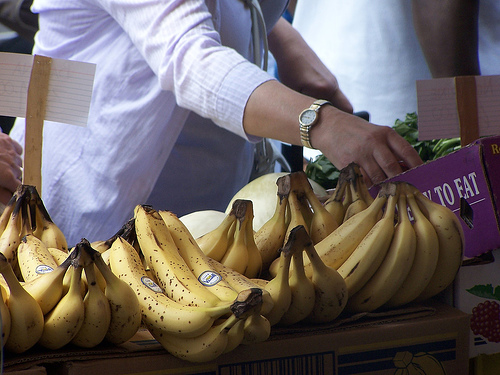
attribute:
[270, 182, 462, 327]
bananas — bunch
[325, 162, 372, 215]
bananas — bunch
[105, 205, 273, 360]
bananas — bunch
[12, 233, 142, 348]
bananas — bunch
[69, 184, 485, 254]
bananas — bunch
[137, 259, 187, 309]
spots — black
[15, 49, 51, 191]
stick — wooden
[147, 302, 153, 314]
spot — brown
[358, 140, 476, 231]
box — purple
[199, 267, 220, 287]
sticker — round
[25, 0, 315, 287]
shirt — white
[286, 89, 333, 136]
watch — gold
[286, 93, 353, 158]
watch — gold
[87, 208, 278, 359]
bananas — yellow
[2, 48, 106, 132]
sign — brown, white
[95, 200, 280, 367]
bananas — bunch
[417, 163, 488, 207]
text — white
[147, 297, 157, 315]
mark — black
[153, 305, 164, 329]
mark — black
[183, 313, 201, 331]
mark — black